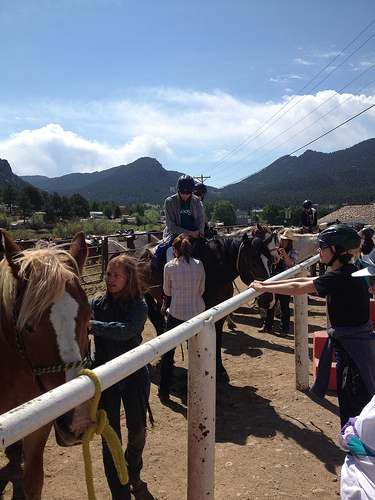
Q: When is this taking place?
A: Daytime.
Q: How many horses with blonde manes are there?
A: One.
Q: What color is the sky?
A: Blue.